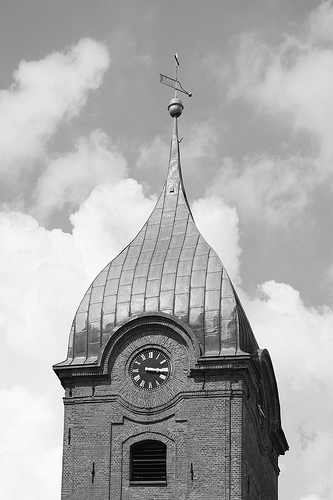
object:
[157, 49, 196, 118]
weathervane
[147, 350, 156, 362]
roman numerals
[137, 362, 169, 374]
time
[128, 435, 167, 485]
vent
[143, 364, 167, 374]
arms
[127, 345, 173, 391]
clock face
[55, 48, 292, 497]
clock tower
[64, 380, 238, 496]
brick wall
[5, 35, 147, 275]
clouds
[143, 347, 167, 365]
numbers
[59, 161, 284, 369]
tiles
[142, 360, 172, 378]
hand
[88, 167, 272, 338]
roofing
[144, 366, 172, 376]
markings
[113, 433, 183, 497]
windows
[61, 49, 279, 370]
steeple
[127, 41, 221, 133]
ornament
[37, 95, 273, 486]
building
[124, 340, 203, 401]
clock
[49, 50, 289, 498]
tower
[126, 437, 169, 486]
window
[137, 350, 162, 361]
numerals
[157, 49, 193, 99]
vane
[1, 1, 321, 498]
sky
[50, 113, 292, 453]
roof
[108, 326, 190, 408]
bricks